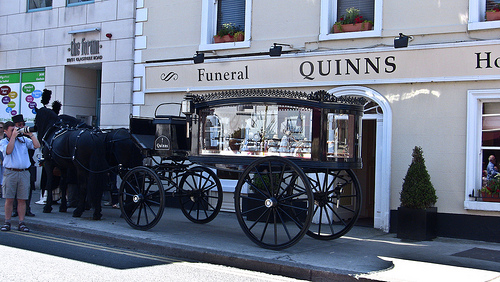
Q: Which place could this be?
A: It is a sidewalk.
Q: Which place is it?
A: It is a sidewalk.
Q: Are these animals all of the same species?
A: Yes, all the animals are horses.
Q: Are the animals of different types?
A: No, all the animals are horses.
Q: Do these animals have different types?
A: No, all the animals are horses.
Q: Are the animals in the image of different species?
A: No, all the animals are horses.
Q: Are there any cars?
A: No, there are no cars.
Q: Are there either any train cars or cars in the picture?
A: No, there are no cars or train cars.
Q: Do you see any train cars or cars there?
A: No, there are no cars or train cars.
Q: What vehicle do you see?
A: The vehicle is a carriage.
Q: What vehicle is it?
A: The vehicle is a carriage.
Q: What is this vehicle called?
A: This is a carriage.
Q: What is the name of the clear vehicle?
A: The vehicle is a carriage.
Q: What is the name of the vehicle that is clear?
A: The vehicle is a carriage.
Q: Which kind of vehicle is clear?
A: The vehicle is a carriage.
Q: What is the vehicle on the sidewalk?
A: The vehicle is a carriage.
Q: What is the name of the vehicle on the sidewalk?
A: The vehicle is a carriage.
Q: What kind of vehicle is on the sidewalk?
A: The vehicle is a carriage.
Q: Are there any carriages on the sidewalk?
A: Yes, there is a carriage on the sidewalk.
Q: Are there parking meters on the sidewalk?
A: No, there is a carriage on the sidewalk.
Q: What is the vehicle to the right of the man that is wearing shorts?
A: The vehicle is a carriage.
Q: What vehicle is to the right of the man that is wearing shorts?
A: The vehicle is a carriage.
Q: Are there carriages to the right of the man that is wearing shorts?
A: Yes, there is a carriage to the right of the man.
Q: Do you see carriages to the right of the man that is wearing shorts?
A: Yes, there is a carriage to the right of the man.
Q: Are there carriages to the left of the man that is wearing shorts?
A: No, the carriage is to the right of the man.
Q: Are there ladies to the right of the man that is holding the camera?
A: No, there is a carriage to the right of the man.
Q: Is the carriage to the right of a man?
A: Yes, the carriage is to the right of a man.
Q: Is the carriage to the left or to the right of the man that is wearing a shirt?
A: The carriage is to the right of the man.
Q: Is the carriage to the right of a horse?
A: Yes, the carriage is to the right of a horse.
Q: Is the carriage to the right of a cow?
A: No, the carriage is to the right of a horse.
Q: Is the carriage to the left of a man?
A: No, the carriage is to the right of a man.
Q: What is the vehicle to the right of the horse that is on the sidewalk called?
A: The vehicle is a carriage.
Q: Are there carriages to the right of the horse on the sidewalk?
A: Yes, there is a carriage to the right of the horse.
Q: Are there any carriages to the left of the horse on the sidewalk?
A: No, the carriage is to the right of the horse.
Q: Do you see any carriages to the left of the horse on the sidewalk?
A: No, the carriage is to the right of the horse.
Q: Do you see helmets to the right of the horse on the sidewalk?
A: No, there is a carriage to the right of the horse.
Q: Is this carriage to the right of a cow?
A: No, the carriage is to the right of the horse.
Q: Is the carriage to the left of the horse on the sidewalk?
A: No, the carriage is to the right of the horse.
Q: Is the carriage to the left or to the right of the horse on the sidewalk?
A: The carriage is to the right of the horse.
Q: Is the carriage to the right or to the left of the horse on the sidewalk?
A: The carriage is to the right of the horse.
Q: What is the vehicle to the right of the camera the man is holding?
A: The vehicle is a carriage.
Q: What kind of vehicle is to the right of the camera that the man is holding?
A: The vehicle is a carriage.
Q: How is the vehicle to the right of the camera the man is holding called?
A: The vehicle is a carriage.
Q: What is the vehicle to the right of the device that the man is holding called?
A: The vehicle is a carriage.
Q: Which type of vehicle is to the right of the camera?
A: The vehicle is a carriage.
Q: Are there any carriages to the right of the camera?
A: Yes, there is a carriage to the right of the camera.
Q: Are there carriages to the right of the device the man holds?
A: Yes, there is a carriage to the right of the camera.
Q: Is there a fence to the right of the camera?
A: No, there is a carriage to the right of the camera.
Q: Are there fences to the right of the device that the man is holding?
A: No, there is a carriage to the right of the camera.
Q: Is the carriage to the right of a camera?
A: Yes, the carriage is to the right of a camera.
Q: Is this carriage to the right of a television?
A: No, the carriage is to the right of a camera.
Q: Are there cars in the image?
A: No, there are no cars.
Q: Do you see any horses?
A: Yes, there are horses.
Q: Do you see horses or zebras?
A: Yes, there are horses.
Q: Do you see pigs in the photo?
A: No, there are no pigs.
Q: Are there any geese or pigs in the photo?
A: No, there are no pigs or geese.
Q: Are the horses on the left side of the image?
A: Yes, the horses are on the left of the image.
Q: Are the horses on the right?
A: No, the horses are on the left of the image.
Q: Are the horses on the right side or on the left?
A: The horses are on the left of the image.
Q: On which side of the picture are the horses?
A: The horses are on the left of the image.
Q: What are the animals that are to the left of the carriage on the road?
A: The animals are horses.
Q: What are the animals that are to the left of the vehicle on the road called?
A: The animals are horses.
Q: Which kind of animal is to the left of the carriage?
A: The animals are horses.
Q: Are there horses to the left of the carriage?
A: Yes, there are horses to the left of the carriage.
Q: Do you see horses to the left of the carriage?
A: Yes, there are horses to the left of the carriage.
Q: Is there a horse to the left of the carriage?
A: Yes, there are horses to the left of the carriage.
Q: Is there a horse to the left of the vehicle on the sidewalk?
A: Yes, there are horses to the left of the carriage.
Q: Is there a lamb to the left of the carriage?
A: No, there are horses to the left of the carriage.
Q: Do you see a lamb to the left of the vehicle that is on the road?
A: No, there are horses to the left of the carriage.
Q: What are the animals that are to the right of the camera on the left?
A: The animals are horses.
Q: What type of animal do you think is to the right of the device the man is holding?
A: The animals are horses.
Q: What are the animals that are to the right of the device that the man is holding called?
A: The animals are horses.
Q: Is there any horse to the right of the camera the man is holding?
A: Yes, there are horses to the right of the camera.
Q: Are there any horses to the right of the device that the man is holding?
A: Yes, there are horses to the right of the camera.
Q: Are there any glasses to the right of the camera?
A: No, there are horses to the right of the camera.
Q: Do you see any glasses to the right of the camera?
A: No, there are horses to the right of the camera.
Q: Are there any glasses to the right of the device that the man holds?
A: No, there are horses to the right of the camera.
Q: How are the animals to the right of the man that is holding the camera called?
A: The animals are horses.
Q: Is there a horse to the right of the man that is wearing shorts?
A: Yes, there are horses to the right of the man.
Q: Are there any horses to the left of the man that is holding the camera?
A: No, the horses are to the right of the man.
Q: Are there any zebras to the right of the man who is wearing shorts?
A: No, there are horses to the right of the man.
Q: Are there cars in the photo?
A: No, there are no cars.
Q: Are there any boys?
A: No, there are no boys.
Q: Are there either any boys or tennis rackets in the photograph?
A: No, there are no boys or tennis rackets.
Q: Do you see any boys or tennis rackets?
A: No, there are no boys or tennis rackets.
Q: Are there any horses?
A: Yes, there is a horse.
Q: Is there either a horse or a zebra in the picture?
A: Yes, there is a horse.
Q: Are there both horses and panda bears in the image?
A: No, there is a horse but no panda bears.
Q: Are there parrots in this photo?
A: No, there are no parrots.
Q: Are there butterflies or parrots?
A: No, there are no parrots or butterflies.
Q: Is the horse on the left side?
A: Yes, the horse is on the left of the image.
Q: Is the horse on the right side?
A: No, the horse is on the left of the image.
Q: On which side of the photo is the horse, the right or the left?
A: The horse is on the left of the image.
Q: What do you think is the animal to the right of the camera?
A: The animal is a horse.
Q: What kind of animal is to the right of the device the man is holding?
A: The animal is a horse.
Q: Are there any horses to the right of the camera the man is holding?
A: Yes, there is a horse to the right of the camera.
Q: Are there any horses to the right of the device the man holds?
A: Yes, there is a horse to the right of the camera.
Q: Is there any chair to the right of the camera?
A: No, there is a horse to the right of the camera.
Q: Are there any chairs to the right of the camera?
A: No, there is a horse to the right of the camera.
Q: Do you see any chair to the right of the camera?
A: No, there is a horse to the right of the camera.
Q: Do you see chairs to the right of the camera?
A: No, there is a horse to the right of the camera.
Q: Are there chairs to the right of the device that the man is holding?
A: No, there is a horse to the right of the camera.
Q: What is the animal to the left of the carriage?
A: The animal is a horse.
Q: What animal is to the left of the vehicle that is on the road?
A: The animal is a horse.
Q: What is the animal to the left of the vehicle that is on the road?
A: The animal is a horse.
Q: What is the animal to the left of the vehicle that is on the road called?
A: The animal is a horse.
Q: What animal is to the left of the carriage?
A: The animal is a horse.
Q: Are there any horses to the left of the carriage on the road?
A: Yes, there is a horse to the left of the carriage.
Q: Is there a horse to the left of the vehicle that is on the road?
A: Yes, there is a horse to the left of the carriage.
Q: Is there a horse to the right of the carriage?
A: No, the horse is to the left of the carriage.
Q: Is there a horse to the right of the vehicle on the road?
A: No, the horse is to the left of the carriage.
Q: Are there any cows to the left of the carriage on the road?
A: No, there is a horse to the left of the carriage.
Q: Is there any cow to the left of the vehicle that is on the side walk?
A: No, there is a horse to the left of the carriage.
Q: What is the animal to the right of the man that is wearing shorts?
A: The animal is a horse.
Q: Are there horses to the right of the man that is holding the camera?
A: Yes, there is a horse to the right of the man.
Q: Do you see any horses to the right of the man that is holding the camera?
A: Yes, there is a horse to the right of the man.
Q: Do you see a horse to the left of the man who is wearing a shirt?
A: No, the horse is to the right of the man.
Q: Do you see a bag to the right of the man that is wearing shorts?
A: No, there is a horse to the right of the man.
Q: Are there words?
A: Yes, there are words.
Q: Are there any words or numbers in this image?
A: Yes, there are words.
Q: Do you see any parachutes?
A: No, there are no parachutes.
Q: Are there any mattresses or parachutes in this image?
A: No, there are no parachutes or mattresses.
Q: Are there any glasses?
A: No, there are no glasses.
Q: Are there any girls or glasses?
A: No, there are no glasses or girls.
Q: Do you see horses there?
A: Yes, there is a horse.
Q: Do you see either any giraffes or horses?
A: Yes, there is a horse.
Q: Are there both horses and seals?
A: No, there is a horse but no seals.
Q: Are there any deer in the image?
A: No, there are no deer.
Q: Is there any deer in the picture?
A: No, there is no deer.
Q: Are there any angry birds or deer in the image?
A: No, there are no deer or angry birds.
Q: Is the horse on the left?
A: Yes, the horse is on the left of the image.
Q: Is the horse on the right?
A: No, the horse is on the left of the image.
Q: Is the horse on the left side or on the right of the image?
A: The horse is on the left of the image.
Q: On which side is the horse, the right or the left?
A: The horse is on the left of the image.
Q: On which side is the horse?
A: The horse is on the left of the image.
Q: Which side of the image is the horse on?
A: The horse is on the left of the image.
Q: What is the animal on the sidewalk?
A: The animal is a horse.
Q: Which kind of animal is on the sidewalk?
A: The animal is a horse.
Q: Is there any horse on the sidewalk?
A: Yes, there is a horse on the sidewalk.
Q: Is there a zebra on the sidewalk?
A: No, there is a horse on the sidewalk.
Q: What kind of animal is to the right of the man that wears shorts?
A: The animal is a horse.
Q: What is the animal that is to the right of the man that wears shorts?
A: The animal is a horse.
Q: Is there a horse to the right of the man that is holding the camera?
A: Yes, there is a horse to the right of the man.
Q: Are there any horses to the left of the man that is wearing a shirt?
A: No, the horse is to the right of the man.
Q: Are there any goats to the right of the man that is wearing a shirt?
A: No, there is a horse to the right of the man.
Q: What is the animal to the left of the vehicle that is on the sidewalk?
A: The animal is a horse.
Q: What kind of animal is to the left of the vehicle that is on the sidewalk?
A: The animal is a horse.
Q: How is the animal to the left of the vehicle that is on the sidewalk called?
A: The animal is a horse.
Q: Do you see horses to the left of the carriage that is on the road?
A: Yes, there is a horse to the left of the carriage.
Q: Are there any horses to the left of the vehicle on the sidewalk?
A: Yes, there is a horse to the left of the carriage.